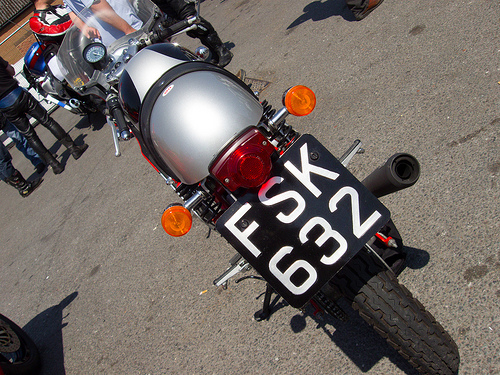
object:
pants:
[3, 89, 68, 157]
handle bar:
[146, 13, 200, 44]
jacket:
[29, 4, 74, 41]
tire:
[0, 311, 35, 372]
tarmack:
[3, 0, 376, 303]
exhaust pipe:
[360, 152, 421, 197]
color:
[223, 142, 384, 296]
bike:
[56, 0, 460, 374]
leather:
[38, 27, 45, 33]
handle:
[151, 17, 200, 45]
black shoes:
[40, 150, 64, 175]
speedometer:
[82, 42, 108, 70]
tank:
[119, 41, 204, 130]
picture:
[0, 0, 499, 375]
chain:
[312, 290, 351, 321]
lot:
[413, 34, 498, 369]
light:
[282, 83, 317, 117]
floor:
[0, 44, 499, 374]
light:
[211, 128, 275, 192]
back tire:
[328, 247, 459, 374]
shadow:
[286, 0, 357, 31]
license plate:
[214, 134, 392, 309]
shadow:
[20, 291, 78, 373]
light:
[161, 205, 193, 237]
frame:
[149, 71, 264, 185]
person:
[0, 56, 89, 173]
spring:
[268, 107, 289, 129]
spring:
[182, 186, 208, 210]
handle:
[107, 98, 129, 141]